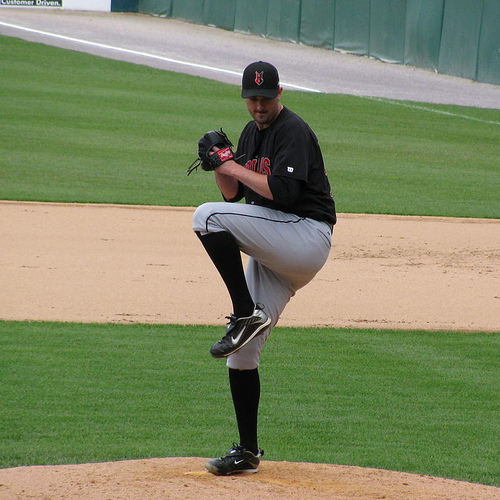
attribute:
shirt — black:
[189, 110, 396, 277]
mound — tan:
[113, 388, 336, 497]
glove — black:
[164, 98, 267, 244]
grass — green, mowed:
[86, 113, 186, 212]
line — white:
[125, 38, 198, 79]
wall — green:
[323, 9, 485, 106]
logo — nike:
[224, 147, 287, 183]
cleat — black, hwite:
[186, 232, 338, 406]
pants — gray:
[176, 161, 393, 494]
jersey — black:
[177, 84, 350, 246]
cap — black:
[220, 41, 291, 112]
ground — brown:
[48, 225, 214, 325]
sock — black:
[174, 224, 291, 493]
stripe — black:
[183, 178, 334, 288]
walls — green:
[292, 6, 499, 140]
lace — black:
[200, 322, 249, 340]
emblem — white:
[276, 160, 319, 184]